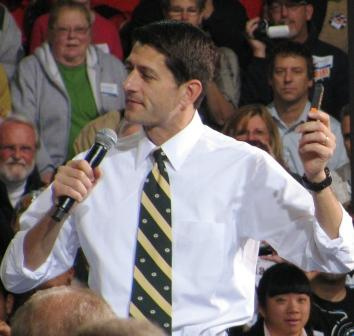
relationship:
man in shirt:
[83, 68, 260, 252] [126, 155, 240, 271]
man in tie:
[83, 68, 260, 252] [128, 159, 191, 275]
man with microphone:
[83, 68, 260, 252] [83, 137, 116, 169]